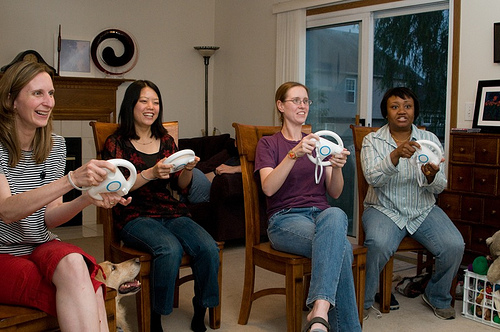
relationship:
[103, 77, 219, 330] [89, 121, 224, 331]
woman sitting on chair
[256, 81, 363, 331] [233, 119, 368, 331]
woman sitting on chair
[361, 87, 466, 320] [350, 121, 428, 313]
woman sitting on chair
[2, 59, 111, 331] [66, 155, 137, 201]
woman holding game controller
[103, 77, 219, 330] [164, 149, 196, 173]
woman holding game controller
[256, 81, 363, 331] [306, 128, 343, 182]
woman holding game controller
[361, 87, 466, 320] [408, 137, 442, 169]
woman holding game controller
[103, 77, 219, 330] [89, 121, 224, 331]
woman sitting in chair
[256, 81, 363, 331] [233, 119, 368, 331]
woman sitting in chair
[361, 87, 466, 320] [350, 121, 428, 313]
woman sitting in chair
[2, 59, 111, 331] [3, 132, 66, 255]
woman wearing a shirt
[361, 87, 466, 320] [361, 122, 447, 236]
woman wearing a shirt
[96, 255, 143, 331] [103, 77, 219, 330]
dog looking at woman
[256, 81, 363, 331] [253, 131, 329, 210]
woman wearing a tee shirt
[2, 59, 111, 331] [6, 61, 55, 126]
woman has a head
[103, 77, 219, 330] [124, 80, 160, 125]
woman has a head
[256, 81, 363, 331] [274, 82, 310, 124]
woman has a head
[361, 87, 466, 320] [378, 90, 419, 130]
woman has a head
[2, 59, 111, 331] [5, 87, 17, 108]
woman has a ear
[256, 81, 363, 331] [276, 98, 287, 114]
woman has a ear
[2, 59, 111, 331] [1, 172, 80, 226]
woman has a arm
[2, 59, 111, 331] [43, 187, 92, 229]
woman has a arm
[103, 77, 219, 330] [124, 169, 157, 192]
woman has a arm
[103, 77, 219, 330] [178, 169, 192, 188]
woman has a arm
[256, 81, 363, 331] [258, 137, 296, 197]
woman has a arm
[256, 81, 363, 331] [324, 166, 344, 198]
woman has a arm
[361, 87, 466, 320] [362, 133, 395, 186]
woman has a arm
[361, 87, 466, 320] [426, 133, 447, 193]
woman has a arm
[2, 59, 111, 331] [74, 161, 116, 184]
woman has a hand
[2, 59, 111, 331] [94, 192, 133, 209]
woman has a hand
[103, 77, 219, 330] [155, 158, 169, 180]
woman has a hand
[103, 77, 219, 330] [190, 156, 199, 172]
woman has a hand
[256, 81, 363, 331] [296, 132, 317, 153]
woman has a hand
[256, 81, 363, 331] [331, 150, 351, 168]
woman has a hand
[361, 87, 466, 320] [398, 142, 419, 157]
woman has a hand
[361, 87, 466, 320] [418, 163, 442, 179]
woman has a hand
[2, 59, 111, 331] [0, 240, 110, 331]
woman has legs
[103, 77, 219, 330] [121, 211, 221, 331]
woman has legs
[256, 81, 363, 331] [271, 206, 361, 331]
woman has legs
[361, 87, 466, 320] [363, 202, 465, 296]
woman has legs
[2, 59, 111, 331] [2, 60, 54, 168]
woman has hair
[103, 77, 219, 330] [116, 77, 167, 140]
woman has hair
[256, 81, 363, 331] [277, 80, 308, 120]
woman has hair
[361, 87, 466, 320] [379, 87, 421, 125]
woman has hair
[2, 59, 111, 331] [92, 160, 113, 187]
woman has fingers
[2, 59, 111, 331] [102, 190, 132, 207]
woman has fingers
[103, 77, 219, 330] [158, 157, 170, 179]
woman has fingers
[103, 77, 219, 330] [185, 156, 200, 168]
woman has fingers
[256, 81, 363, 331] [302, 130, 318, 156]
woman has fingers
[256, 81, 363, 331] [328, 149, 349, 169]
woman has fingers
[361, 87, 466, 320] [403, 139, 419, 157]
woman has fingers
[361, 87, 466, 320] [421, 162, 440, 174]
woman has fingers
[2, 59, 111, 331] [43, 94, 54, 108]
woman has a nose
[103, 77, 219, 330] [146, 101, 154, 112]
woman has a nose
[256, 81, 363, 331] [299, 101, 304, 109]
woman has a nose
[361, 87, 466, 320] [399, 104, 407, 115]
woman has a nose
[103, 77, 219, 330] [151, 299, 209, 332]
woman has feet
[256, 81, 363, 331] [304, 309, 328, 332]
woman has feet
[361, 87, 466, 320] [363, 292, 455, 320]
woman has feet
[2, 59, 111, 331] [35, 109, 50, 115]
woman has teeth